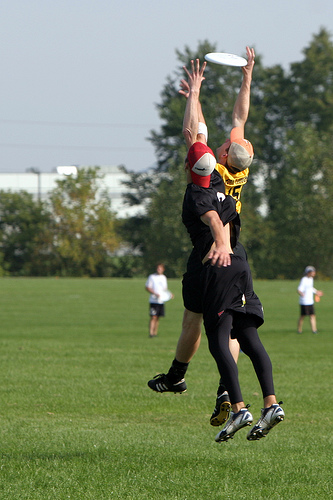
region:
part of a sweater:
[238, 286, 260, 310]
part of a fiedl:
[121, 437, 147, 466]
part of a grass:
[127, 447, 152, 476]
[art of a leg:
[227, 377, 242, 404]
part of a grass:
[141, 468, 165, 497]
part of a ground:
[151, 466, 170, 486]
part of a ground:
[114, 451, 138, 469]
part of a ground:
[113, 413, 142, 440]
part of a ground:
[163, 464, 182, 485]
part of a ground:
[154, 433, 174, 458]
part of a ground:
[113, 426, 142, 460]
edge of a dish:
[225, 61, 236, 70]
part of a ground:
[122, 420, 150, 453]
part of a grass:
[111, 431, 140, 476]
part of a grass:
[133, 456, 155, 478]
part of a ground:
[132, 436, 160, 472]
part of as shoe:
[230, 415, 241, 435]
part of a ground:
[129, 424, 158, 460]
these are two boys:
[164, 115, 273, 439]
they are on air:
[157, 73, 277, 428]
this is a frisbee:
[206, 47, 248, 69]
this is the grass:
[80, 419, 172, 486]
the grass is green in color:
[67, 419, 190, 498]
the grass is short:
[66, 413, 188, 496]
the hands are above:
[180, 65, 257, 125]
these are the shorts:
[193, 272, 258, 309]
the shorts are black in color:
[216, 265, 246, 308]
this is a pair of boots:
[227, 405, 283, 435]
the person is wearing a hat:
[188, 145, 213, 185]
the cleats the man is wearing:
[216, 408, 249, 435]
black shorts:
[148, 302, 165, 315]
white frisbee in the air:
[201, 51, 249, 70]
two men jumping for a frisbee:
[146, 44, 285, 447]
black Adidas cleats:
[147, 371, 186, 395]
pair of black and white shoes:
[210, 400, 285, 441]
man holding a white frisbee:
[142, 260, 173, 337]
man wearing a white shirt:
[295, 263, 324, 334]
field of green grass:
[0, 275, 331, 498]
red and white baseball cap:
[185, 141, 216, 189]